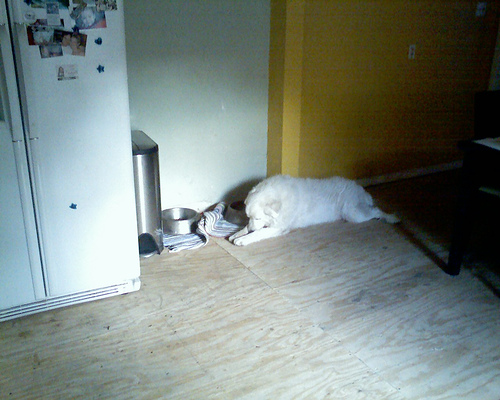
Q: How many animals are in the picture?
A: One.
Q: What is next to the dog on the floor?
A: Dog bowl.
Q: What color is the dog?
A: White.